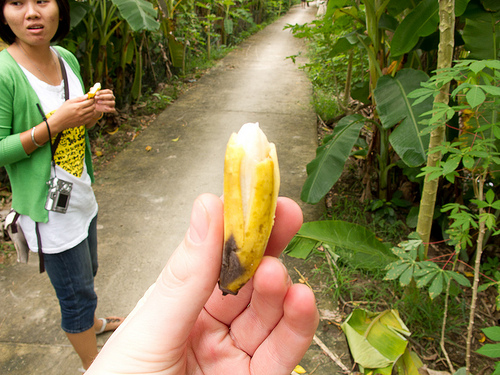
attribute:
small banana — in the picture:
[217, 120, 281, 296]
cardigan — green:
[1, 40, 93, 219]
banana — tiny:
[212, 115, 284, 299]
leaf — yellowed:
[344, 301, 414, 371]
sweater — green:
[3, 51, 104, 228]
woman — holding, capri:
[1, 3, 131, 373]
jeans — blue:
[39, 212, 97, 332]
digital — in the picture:
[32, 113, 84, 231]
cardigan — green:
[2, 46, 128, 275]